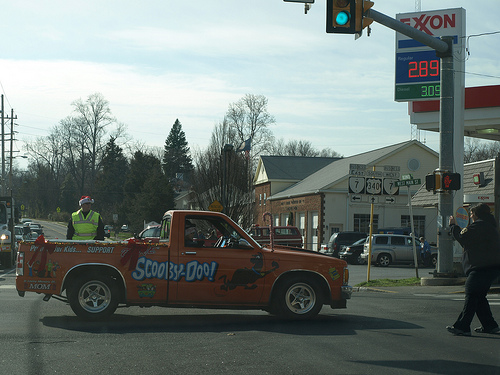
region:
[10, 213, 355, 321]
a truck sitting in the parking lot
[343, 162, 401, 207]
assorted street signs on a pole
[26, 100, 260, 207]
a bunch of trees sitting next to each other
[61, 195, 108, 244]
a man wearing a santa hat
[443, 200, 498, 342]
a woman taking a photo of the truck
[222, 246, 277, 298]
Scooby Doo painted on the truck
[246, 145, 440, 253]
some buildings next to the road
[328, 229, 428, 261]
some cars parked next the building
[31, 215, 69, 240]
the road for cars to drive on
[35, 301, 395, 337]
the shadow of the truck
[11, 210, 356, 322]
orange Scooby Doo truck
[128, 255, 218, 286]
letters on side of truck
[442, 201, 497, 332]
person taking photo of truck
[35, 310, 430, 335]
shadow of orange truck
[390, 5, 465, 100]
gas station sign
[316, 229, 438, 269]
four cars parked in a line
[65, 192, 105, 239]
person wearing santa hat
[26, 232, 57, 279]
red bow on truck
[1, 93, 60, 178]
telephone poles and lines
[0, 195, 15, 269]
part of truck with headlights on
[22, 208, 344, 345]
orange and white truck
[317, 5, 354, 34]
green signal light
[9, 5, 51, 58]
white clouds in blue sky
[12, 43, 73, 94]
white clouds in blue sky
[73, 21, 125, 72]
white clouds in blue sky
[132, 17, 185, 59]
white clouds in blue sky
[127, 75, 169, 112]
white clouds in blue sky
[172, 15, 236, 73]
white clouds in blue sky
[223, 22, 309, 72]
white clouds in blue sky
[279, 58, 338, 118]
white clouds in blue sky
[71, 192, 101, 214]
a man wearing a santa hat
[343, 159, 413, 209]
three black and white road signs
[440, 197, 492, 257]
a woman taking a picture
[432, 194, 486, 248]
a woman holding a camera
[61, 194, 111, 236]
a man wearing a yellow safety vest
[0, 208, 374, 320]
a orange truck with cartoons painted on it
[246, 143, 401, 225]
a building with a shingled roof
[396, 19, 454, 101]
a digital sign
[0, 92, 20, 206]
wood electrical poles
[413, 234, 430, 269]
a person standing next to a parked car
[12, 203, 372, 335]
this is a pick up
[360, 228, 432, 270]
this is a car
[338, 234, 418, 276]
this is a car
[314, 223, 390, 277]
this is a car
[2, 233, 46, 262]
this is a car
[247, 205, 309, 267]
this is a car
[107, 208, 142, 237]
this is a car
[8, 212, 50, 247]
this is a car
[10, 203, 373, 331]
this is a car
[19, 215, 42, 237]
this is a car